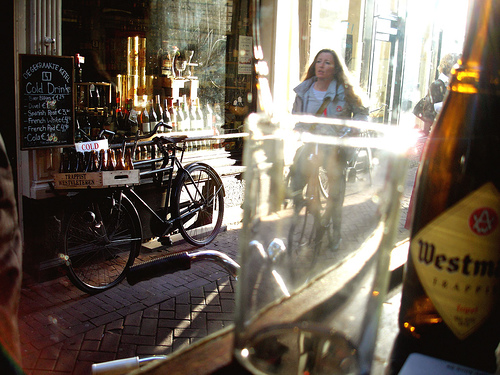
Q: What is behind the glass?
A: The woman.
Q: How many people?
A: 1.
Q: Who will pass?
A: The lady.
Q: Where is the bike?
A: Sidewalk.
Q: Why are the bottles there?
A: To sell.